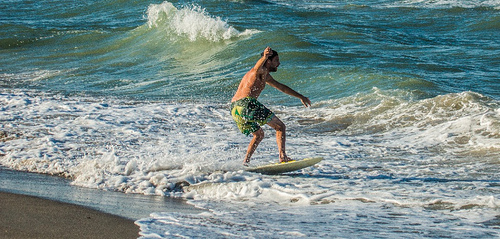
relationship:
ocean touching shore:
[0, 0, 499, 237] [1, 166, 208, 239]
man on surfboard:
[229, 46, 310, 167] [247, 155, 324, 173]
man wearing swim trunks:
[229, 46, 310, 167] [229, 97, 273, 135]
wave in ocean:
[105, 2, 329, 87] [0, 0, 499, 237]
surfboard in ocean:
[247, 155, 324, 173] [0, 0, 499, 237]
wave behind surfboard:
[105, 2, 329, 87] [247, 155, 324, 173]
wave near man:
[105, 2, 329, 87] [229, 46, 310, 167]